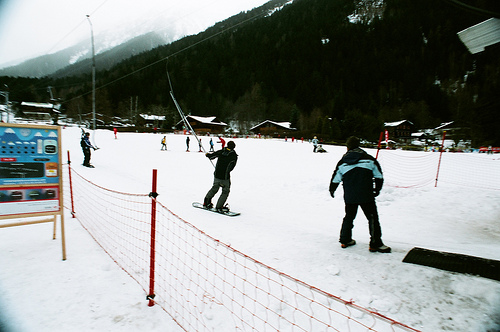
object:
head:
[345, 136, 360, 151]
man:
[328, 136, 391, 254]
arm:
[328, 163, 345, 192]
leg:
[339, 202, 360, 245]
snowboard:
[192, 202, 240, 217]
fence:
[59, 160, 424, 332]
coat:
[328, 149, 384, 204]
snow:
[115, 150, 184, 188]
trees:
[240, 59, 341, 121]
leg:
[358, 199, 385, 246]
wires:
[59, 1, 290, 104]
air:
[0, 45, 22, 62]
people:
[202, 140, 238, 212]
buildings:
[383, 119, 417, 142]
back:
[458, 19, 498, 55]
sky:
[83, 4, 151, 35]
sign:
[0, 122, 63, 216]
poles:
[183, 115, 216, 169]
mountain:
[269, 22, 415, 113]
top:
[205, 147, 238, 177]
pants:
[204, 176, 231, 209]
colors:
[331, 158, 383, 183]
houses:
[250, 119, 297, 139]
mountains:
[361, 0, 500, 111]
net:
[61, 164, 420, 332]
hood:
[342, 148, 363, 164]